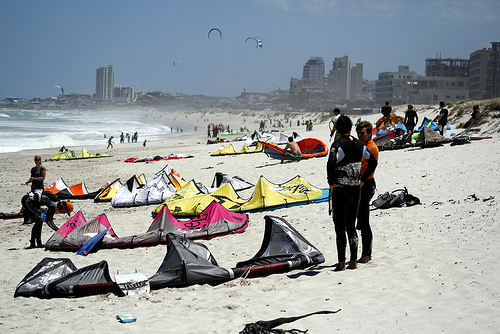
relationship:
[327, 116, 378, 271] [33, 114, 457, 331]
people stand on beach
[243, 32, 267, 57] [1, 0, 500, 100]
kite in blue sky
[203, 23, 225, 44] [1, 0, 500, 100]
kite in blue sky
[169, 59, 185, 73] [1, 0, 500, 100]
kite in blue sky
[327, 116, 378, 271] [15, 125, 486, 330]
people standing on beach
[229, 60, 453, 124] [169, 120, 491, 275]
buildings off of beach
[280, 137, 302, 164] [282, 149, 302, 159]
people in shorts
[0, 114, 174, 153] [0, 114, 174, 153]
ocean in ocean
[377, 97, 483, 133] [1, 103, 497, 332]
people on beach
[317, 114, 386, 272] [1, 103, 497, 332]
people on beach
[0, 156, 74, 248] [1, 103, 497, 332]
people on beach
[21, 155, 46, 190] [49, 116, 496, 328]
people on beach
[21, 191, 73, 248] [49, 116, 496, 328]
man on beach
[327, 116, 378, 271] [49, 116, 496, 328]
people on beach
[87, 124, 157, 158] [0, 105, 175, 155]
people near ocean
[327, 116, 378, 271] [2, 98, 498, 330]
people standing in sand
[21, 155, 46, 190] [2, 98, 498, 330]
people standing in sand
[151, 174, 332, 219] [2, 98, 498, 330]
kite laying in sand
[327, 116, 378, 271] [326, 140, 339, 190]
people has hands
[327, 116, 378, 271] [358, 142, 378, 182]
people has hands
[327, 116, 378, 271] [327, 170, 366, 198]
people has hips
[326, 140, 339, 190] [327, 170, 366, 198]
hands on hips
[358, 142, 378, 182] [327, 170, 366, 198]
hands on hips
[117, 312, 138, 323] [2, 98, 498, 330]
object laying on sand